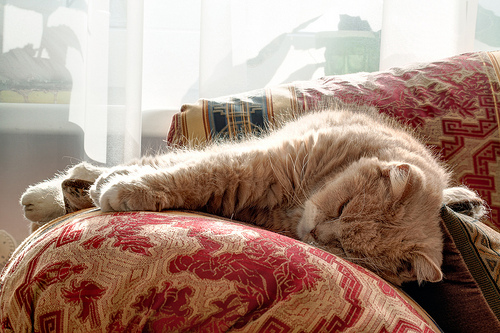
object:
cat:
[21, 94, 459, 289]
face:
[297, 178, 379, 276]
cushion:
[166, 48, 499, 234]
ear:
[388, 162, 414, 209]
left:
[379, 248, 444, 285]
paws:
[99, 193, 108, 210]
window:
[2, 0, 500, 104]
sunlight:
[0, 1, 499, 136]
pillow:
[400, 202, 500, 332]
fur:
[122, 88, 457, 288]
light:
[329, 155, 438, 203]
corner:
[63, 198, 85, 215]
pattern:
[441, 94, 498, 140]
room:
[1, 0, 499, 332]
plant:
[0, 24, 84, 105]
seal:
[247, 15, 384, 85]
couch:
[0, 48, 498, 330]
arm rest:
[0, 205, 433, 332]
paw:
[20, 190, 45, 208]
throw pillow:
[0, 206, 451, 332]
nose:
[310, 219, 337, 245]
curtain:
[0, 0, 498, 190]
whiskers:
[260, 153, 309, 209]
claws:
[120, 200, 135, 212]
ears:
[405, 247, 445, 283]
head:
[295, 153, 444, 289]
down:
[340, 222, 457, 289]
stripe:
[229, 93, 249, 141]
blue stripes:
[209, 101, 225, 131]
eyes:
[336, 195, 354, 220]